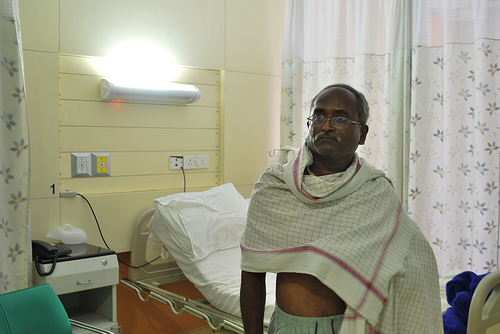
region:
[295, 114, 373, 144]
man wearing glasses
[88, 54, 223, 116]
light on a wall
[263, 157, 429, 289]
man wearing a plaid robe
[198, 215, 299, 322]
man next to a hospital bed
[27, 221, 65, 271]
telephone on a night stand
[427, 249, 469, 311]
blue shirt on top on bed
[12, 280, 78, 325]
green chair in a room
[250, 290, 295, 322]
man with gray shorts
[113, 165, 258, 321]
Hospital bed in a room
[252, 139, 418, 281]
plaid robe on a man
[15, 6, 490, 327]
Man in a hospital room.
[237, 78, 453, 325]
Man with blanket around his shoulders.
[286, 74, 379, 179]
Man wearing glasses.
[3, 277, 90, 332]
A chair with green top.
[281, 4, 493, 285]
Curtains on right side for privacy.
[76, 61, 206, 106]
A light fixture turned on.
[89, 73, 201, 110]
Light fixture mounted on wall.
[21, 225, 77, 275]
A black telephone.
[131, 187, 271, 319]
A hospital bed.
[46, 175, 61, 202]
The number 1 on the wall.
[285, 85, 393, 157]
man is wearing glasses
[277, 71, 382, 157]
man has brown skin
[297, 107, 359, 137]
the eyes are open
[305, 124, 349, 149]
the man has a mustache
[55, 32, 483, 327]
man is in the hospital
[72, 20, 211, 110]
the light is on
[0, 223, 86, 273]
the phone is on the table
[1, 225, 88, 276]
the phone is black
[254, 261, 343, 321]
the stomach is showing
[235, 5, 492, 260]
the curtain in the background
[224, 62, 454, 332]
indian man in hospital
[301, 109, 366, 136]
glasses on a man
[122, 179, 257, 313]
hospital bed with white sheets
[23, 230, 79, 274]
black phone on a table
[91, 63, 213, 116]
illuminated light on wall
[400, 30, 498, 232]
curtains in a hospital room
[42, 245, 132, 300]
drawer to a table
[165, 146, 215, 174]
outlets on a wall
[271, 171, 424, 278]
sheet on a man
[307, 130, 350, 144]
moustache on a man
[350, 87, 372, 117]
man with grey hair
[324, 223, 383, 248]
sheet around mans neck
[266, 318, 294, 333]
boxers on mans waist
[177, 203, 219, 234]
white pillow on bed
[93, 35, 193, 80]
light over top bed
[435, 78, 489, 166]
curtain in hospital room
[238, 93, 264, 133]
beige paint on wall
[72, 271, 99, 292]
silver knob on drawer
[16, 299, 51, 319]
green back of chair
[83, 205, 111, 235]
black cord hanging from wall